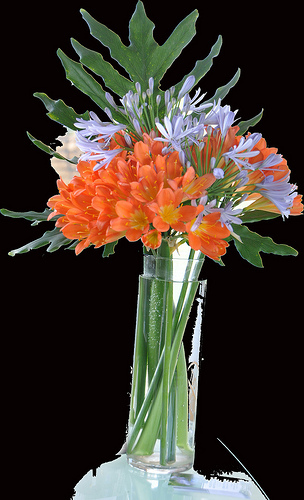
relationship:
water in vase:
[124, 271, 206, 475] [119, 268, 207, 483]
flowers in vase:
[34, 67, 303, 268] [119, 268, 207, 483]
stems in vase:
[123, 252, 206, 454] [119, 268, 207, 483]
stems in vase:
[160, 257, 174, 470] [119, 268, 207, 483]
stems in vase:
[115, 240, 197, 456] [119, 268, 207, 483]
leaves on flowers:
[1, 4, 301, 278] [34, 67, 303, 268]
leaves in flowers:
[1, 4, 301, 278] [34, 67, 303, 268]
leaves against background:
[1, 4, 301, 278] [2, 1, 304, 500]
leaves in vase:
[1, 4, 301, 278] [119, 268, 207, 483]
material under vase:
[63, 431, 272, 500] [119, 268, 207, 483]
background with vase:
[2, 1, 304, 500] [119, 268, 207, 483]